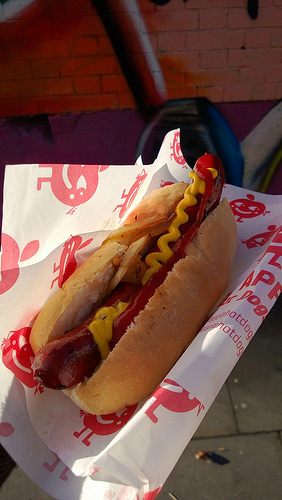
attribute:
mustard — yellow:
[90, 167, 217, 365]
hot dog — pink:
[32, 152, 224, 390]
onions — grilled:
[107, 234, 160, 289]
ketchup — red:
[113, 164, 212, 342]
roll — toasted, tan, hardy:
[27, 183, 240, 417]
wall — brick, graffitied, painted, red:
[1, 0, 280, 116]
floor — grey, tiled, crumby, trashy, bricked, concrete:
[0, 298, 279, 499]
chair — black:
[130, 95, 244, 188]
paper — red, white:
[0, 127, 281, 500]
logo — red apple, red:
[228, 191, 268, 226]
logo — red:
[36, 163, 113, 212]